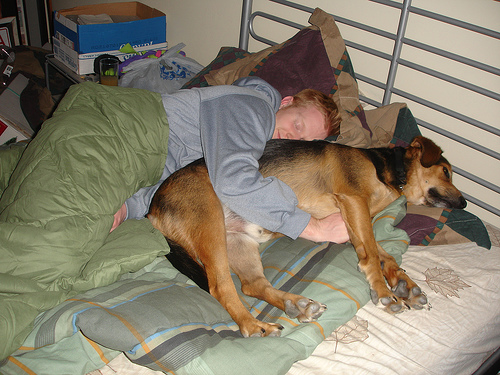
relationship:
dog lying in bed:
[142, 135, 467, 339] [368, 332, 403, 359]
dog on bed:
[142, 135, 467, 339] [62, 55, 497, 362]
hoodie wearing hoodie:
[109, 76, 312, 242] [99, 85, 299, 250]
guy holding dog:
[0, 75, 350, 245] [136, 96, 469, 355]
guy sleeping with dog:
[61, 46, 348, 260] [146, 98, 461, 335]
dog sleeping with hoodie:
[153, 135, 477, 333] [109, 76, 312, 242]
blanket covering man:
[8, 101, 235, 358] [76, 73, 353, 248]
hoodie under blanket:
[109, 76, 312, 242] [0, 75, 170, 360]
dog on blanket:
[153, 135, 477, 333] [9, 194, 411, 372]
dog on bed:
[153, 135, 477, 333] [1, 139, 498, 371]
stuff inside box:
[54, 1, 155, 35] [44, 4, 171, 79]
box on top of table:
[44, 4, 171, 79] [11, 43, 81, 141]